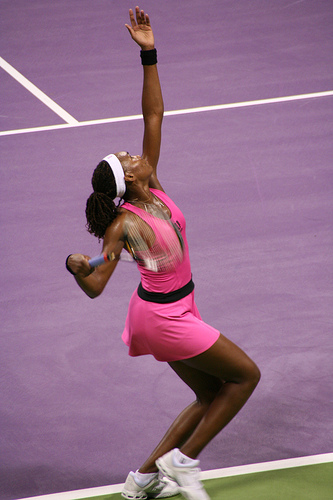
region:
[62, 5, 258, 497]
Woman playing tennis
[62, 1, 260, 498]
A woman in the middle of serving a tennis ball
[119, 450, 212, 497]
White tennis shoes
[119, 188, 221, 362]
Pink and black tennis dress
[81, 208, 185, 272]
Tennis racket with blue handle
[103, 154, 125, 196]
Whte headband on womans head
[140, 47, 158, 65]
Black wrist band on wrist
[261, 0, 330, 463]
Purple and white tennis court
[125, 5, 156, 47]
A black woman's hand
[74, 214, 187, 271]
Tennis racket in motion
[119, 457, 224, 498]
pair of white tennis shoes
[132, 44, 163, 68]
black wrist band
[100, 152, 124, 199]
white head band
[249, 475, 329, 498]
green turf on tennis court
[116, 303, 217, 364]
pink tennis skirt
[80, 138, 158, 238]
women with black braided hair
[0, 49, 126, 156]
white stripes on tennis court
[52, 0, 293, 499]
a tennis player in pink shirt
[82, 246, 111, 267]
blue and red tennis racquet handle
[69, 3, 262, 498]
tennis player preparing to hit ball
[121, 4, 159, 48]
the hand of a woman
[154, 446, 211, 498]
a white shoe on the woman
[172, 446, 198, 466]
a white sock on the woman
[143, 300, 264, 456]
the leg of a woman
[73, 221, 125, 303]
the arm of a woman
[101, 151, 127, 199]
a white head band on the woman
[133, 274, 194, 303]
a black belt on the woman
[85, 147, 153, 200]
the head of a woman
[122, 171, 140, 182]
the ear of a woman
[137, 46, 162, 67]
a black wrist band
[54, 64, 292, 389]
lady playing tennis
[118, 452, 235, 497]
shoes of tennis player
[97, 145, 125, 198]
headband of tennis player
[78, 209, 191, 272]
tennis racket held by player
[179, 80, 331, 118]
line on tennis court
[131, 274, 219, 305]
belt worn by tennis player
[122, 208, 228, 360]
outfit worn by tennis player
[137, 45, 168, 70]
wristband worn by tennis player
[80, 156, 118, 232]
hair of tennis player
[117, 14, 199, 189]
tennis players arm straight out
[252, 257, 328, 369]
the ground is purple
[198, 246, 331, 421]
the ground is purple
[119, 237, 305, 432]
the ground is purple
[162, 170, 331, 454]
the ground is purple